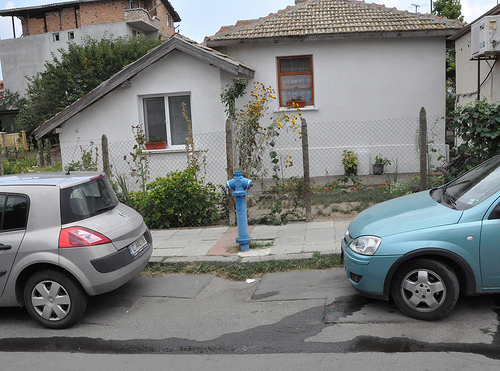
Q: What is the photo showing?
A: It is showing a street.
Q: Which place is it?
A: It is a street.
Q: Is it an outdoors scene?
A: Yes, it is outdoors.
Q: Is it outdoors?
A: Yes, it is outdoors.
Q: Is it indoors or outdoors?
A: It is outdoors.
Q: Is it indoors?
A: No, it is outdoors.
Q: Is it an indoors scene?
A: No, it is outdoors.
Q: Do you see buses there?
A: No, there are no buses.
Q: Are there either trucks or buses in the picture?
A: No, there are no buses or trucks.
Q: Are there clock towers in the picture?
A: No, there are no clock towers.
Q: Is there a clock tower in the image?
A: No, there are no clock towers.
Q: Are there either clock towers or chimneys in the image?
A: No, there are no clock towers or chimneys.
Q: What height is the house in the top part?
A: The house is tall.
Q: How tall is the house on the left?
A: The house is tall.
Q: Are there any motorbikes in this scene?
A: No, there are no motorbikes.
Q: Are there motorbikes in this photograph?
A: No, there are no motorbikes.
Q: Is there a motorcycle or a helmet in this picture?
A: No, there are no motorcycles or helmets.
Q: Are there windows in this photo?
A: Yes, there is a window.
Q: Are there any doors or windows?
A: Yes, there is a window.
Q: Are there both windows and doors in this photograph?
A: No, there is a window but no doors.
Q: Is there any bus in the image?
A: No, there are no buses.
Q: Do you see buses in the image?
A: No, there are no buses.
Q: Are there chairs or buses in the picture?
A: No, there are no buses or chairs.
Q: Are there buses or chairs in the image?
A: No, there are no buses or chairs.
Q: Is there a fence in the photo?
A: Yes, there is a fence.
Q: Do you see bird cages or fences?
A: Yes, there is a fence.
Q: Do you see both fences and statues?
A: No, there is a fence but no statues.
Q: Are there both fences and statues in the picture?
A: No, there is a fence but no statues.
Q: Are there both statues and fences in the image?
A: No, there is a fence but no statues.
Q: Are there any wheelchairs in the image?
A: No, there are no wheelchairs.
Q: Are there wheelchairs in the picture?
A: No, there are no wheelchairs.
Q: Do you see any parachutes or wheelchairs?
A: No, there are no wheelchairs or parachutes.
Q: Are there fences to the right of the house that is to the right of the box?
A: Yes, there is a fence to the right of the house.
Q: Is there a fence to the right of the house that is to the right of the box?
A: Yes, there is a fence to the right of the house.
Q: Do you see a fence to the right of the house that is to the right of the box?
A: Yes, there is a fence to the right of the house.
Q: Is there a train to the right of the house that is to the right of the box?
A: No, there is a fence to the right of the house.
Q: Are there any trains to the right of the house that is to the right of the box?
A: No, there is a fence to the right of the house.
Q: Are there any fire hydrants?
A: Yes, there is a fire hydrant.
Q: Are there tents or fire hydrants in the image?
A: Yes, there is a fire hydrant.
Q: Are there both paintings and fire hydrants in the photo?
A: No, there is a fire hydrant but no paintings.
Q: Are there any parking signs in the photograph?
A: No, there are no parking signs.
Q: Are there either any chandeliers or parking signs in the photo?
A: No, there are no parking signs or chandeliers.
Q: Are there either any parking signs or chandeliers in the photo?
A: No, there are no parking signs or chandeliers.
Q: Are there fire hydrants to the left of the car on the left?
A: No, the fire hydrant is to the right of the car.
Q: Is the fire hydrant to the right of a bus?
A: No, the fire hydrant is to the right of the car.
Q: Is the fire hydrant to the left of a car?
A: No, the fire hydrant is to the right of a car.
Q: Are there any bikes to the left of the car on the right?
A: No, there is a fire hydrant to the left of the car.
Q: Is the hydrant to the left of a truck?
A: No, the hydrant is to the left of the car.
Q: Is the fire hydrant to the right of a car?
A: No, the fire hydrant is to the left of a car.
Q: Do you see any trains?
A: No, there are no trains.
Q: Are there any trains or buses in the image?
A: No, there are no trains or buses.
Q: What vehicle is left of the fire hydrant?
A: The vehicle is a car.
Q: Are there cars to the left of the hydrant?
A: Yes, there is a car to the left of the hydrant.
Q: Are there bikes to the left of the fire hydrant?
A: No, there is a car to the left of the fire hydrant.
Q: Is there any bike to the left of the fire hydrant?
A: No, there is a car to the left of the fire hydrant.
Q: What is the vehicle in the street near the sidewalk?
A: The vehicle is a car.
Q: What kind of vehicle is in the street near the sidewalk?
A: The vehicle is a car.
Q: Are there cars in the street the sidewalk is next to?
A: Yes, there is a car in the street.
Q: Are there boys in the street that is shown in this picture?
A: No, there is a car in the street.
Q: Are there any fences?
A: Yes, there is a fence.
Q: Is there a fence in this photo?
A: Yes, there is a fence.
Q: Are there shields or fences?
A: Yes, there is a fence.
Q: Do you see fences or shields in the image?
A: Yes, there is a fence.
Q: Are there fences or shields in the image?
A: Yes, there is a fence.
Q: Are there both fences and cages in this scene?
A: No, there is a fence but no cages.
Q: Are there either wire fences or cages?
A: Yes, there is a wire fence.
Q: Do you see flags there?
A: No, there are no flags.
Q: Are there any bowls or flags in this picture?
A: No, there are no flags or bowls.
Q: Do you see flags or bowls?
A: No, there are no flags or bowls.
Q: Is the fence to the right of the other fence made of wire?
A: Yes, the fence is made of wire.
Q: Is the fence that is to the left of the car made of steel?
A: No, the fence is made of wire.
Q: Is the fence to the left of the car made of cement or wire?
A: The fence is made of wire.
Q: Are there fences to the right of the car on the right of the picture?
A: No, the fence is to the left of the car.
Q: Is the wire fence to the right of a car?
A: No, the fence is to the left of a car.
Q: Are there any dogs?
A: No, there are no dogs.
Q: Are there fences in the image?
A: Yes, there is a fence.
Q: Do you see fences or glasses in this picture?
A: Yes, there is a fence.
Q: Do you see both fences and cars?
A: Yes, there are both a fence and a car.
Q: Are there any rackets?
A: No, there are no rackets.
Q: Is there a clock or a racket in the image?
A: No, there are no rackets or clocks.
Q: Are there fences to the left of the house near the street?
A: Yes, there is a fence to the left of the house.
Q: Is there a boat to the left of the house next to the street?
A: No, there is a fence to the left of the house.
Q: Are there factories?
A: No, there are no factories.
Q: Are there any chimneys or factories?
A: No, there are no factories or chimneys.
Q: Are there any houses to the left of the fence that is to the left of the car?
A: Yes, there is a house to the left of the fence.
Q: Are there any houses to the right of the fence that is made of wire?
A: No, the house is to the left of the fence.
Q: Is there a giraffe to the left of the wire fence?
A: No, there is a house to the left of the fence.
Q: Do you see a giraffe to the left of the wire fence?
A: No, there is a house to the left of the fence.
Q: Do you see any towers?
A: No, there are no towers.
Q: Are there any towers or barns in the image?
A: No, there are no towers or barns.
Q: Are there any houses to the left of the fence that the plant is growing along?
A: Yes, there is a house to the left of the fence.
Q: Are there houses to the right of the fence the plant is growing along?
A: No, the house is to the left of the fence.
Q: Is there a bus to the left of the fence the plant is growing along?
A: No, there is a house to the left of the fence.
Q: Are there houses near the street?
A: Yes, there is a house near the street.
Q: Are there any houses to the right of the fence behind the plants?
A: Yes, there is a house to the right of the fence.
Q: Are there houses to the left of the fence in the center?
A: No, the house is to the right of the fence.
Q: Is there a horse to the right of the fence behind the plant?
A: No, there is a house to the right of the fence.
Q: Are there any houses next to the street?
A: Yes, there is a house next to the street.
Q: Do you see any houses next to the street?
A: Yes, there is a house next to the street.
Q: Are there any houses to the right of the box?
A: Yes, there is a house to the right of the box.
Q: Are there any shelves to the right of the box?
A: No, there is a house to the right of the box.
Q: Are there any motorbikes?
A: No, there are no motorbikes.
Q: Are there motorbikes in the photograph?
A: No, there are no motorbikes.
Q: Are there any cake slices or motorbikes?
A: No, there are no motorbikes or cake slices.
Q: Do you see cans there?
A: No, there are no cans.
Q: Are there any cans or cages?
A: No, there are no cans or cages.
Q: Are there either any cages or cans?
A: No, there are no cans or cages.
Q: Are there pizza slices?
A: No, there are no pizza slices.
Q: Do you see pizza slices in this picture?
A: No, there are no pizza slices.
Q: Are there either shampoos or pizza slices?
A: No, there are no pizza slices or shampoos.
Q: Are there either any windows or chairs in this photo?
A: Yes, there is a window.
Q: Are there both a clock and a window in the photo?
A: No, there is a window but no clocks.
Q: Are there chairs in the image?
A: No, there are no chairs.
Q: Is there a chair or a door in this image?
A: No, there are no chairs or doors.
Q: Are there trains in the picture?
A: No, there are no trains.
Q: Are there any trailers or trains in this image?
A: No, there are no trains or trailers.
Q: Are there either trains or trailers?
A: No, there are no trains or trailers.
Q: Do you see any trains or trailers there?
A: No, there are no trains or trailers.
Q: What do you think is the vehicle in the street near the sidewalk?
A: The vehicle is a car.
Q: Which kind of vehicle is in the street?
A: The vehicle is a car.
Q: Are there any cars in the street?
A: Yes, there is a car in the street.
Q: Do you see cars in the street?
A: Yes, there is a car in the street.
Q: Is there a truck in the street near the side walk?
A: No, there is a car in the street.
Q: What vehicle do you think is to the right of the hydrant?
A: The vehicle is a car.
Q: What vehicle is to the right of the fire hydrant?
A: The vehicle is a car.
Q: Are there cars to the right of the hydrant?
A: Yes, there is a car to the right of the hydrant.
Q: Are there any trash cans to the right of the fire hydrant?
A: No, there is a car to the right of the fire hydrant.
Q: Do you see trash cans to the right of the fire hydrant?
A: No, there is a car to the right of the fire hydrant.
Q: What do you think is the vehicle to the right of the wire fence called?
A: The vehicle is a car.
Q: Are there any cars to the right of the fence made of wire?
A: Yes, there is a car to the right of the fence.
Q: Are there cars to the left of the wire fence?
A: No, the car is to the right of the fence.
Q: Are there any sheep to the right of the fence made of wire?
A: No, there is a car to the right of the fence.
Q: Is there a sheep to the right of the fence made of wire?
A: No, there is a car to the right of the fence.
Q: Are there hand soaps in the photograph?
A: No, there are no hand soaps.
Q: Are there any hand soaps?
A: No, there are no hand soaps.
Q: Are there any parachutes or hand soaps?
A: No, there are no hand soaps or parachutes.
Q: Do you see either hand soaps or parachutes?
A: No, there are no hand soaps or parachutes.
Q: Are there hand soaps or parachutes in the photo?
A: No, there are no hand soaps or parachutes.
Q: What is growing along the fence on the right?
A: The plant is growing along the fence.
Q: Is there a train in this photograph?
A: No, there are no trains.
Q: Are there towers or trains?
A: No, there are no trains or towers.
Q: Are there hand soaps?
A: No, there are no hand soaps.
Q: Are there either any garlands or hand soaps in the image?
A: No, there are no hand soaps or garlands.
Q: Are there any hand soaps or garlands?
A: No, there are no hand soaps or garlands.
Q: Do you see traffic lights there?
A: No, there are no traffic lights.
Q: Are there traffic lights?
A: No, there are no traffic lights.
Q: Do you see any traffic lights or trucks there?
A: No, there are no traffic lights or trucks.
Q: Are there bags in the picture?
A: No, there are no bags.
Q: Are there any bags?
A: No, there are no bags.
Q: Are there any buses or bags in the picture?
A: No, there are no bags or buses.